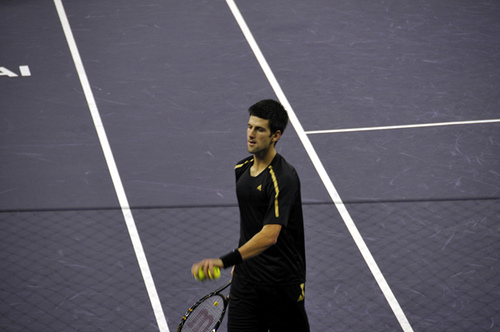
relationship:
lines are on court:
[268, 84, 377, 189] [12, 10, 497, 319]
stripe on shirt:
[259, 168, 286, 224] [214, 150, 339, 310]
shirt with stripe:
[229, 153, 311, 279] [251, 161, 298, 227]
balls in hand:
[196, 224, 237, 292] [174, 181, 302, 291]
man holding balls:
[206, 93, 306, 328] [171, 224, 241, 298]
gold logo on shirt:
[253, 181, 273, 201] [229, 161, 298, 228]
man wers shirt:
[206, 93, 306, 328] [223, 165, 294, 240]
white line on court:
[349, 250, 400, 270] [331, 243, 455, 291]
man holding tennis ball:
[206, 93, 306, 328] [184, 255, 224, 284]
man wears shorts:
[206, 93, 306, 328] [228, 300, 313, 330]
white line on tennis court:
[349, 250, 400, 270] [289, 70, 499, 330]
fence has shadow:
[2, 191, 497, 330] [3, 187, 488, 267]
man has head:
[206, 93, 306, 328] [232, 93, 297, 166]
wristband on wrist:
[222, 245, 245, 268] [212, 234, 252, 278]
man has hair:
[206, 93, 306, 328] [246, 93, 290, 143]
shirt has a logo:
[229, 153, 311, 279] [253, 181, 265, 191]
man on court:
[206, 93, 306, 328] [12, 10, 497, 319]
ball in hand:
[205, 265, 222, 284] [189, 255, 222, 282]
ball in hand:
[189, 265, 208, 285] [189, 255, 222, 282]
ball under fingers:
[189, 265, 208, 285] [190, 257, 217, 279]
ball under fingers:
[205, 265, 222, 284] [190, 257, 217, 279]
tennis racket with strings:
[175, 280, 237, 328] [181, 293, 224, 330]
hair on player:
[247, 96, 287, 134] [192, 93, 314, 330]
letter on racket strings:
[190, 307, 213, 330] [176, 290, 229, 330]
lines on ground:
[54, 1, 497, 330] [1, 1, 497, 328]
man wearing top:
[206, 93, 306, 328] [220, 153, 306, 287]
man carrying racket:
[206, 93, 306, 328] [120, 236, 247, 328]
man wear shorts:
[206, 93, 306, 328] [186, 252, 312, 324]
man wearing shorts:
[206, 93, 306, 328] [178, 271, 333, 323]